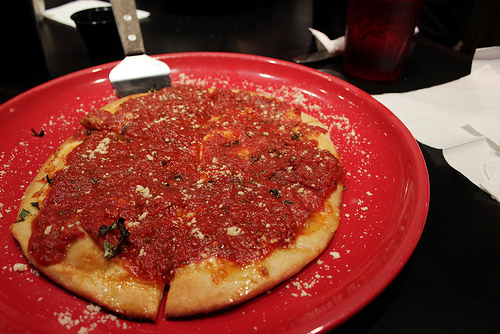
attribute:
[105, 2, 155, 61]
handle — wood 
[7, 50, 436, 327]
plate — Large , red, round 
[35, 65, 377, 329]
pizza — Small  , single serve  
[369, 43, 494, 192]
napkin — White  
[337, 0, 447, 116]
cup — red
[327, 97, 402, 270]
parmesan — Sprinkles 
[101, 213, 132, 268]
basil — Ribbon , cut  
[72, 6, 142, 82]
ramiken — Black 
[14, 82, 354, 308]
pizza — tomato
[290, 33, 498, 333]
table — dark 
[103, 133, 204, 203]
spices — red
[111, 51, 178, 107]
spade — metallic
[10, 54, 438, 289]
table — black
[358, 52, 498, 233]
cloth — white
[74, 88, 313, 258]
sauce — red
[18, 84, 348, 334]
pizza — sitting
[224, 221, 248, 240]
cheese — white, sprinkled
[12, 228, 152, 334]
crust — golden, brown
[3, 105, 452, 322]
plate — red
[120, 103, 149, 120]
handle — wood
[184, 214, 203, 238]
cheese — white, sprinkled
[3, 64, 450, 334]
plate — red, sitting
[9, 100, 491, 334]
surface — black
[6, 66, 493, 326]
surface — black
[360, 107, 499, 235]
napkin — white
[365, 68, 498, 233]
tissue — white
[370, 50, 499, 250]
tissue — white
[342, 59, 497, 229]
tissue — white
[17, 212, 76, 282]
tomatoes — crushed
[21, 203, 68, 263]
tomatoes — crushed, baked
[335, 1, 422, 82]
plastic cup — red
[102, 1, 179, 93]
serving utensil — silver, wood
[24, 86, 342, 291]
tomato paste — red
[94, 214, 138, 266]
herb — green